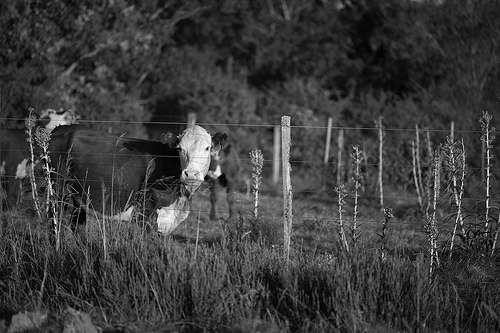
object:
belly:
[72, 193, 137, 222]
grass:
[255, 257, 337, 325]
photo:
[9, 6, 494, 325]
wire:
[241, 114, 346, 135]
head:
[168, 120, 218, 188]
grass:
[208, 246, 270, 297]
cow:
[45, 124, 227, 233]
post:
[274, 113, 295, 266]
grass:
[30, 223, 139, 329]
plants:
[94, 190, 140, 259]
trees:
[76, 62, 153, 121]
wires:
[33, 151, 282, 162]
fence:
[6, 94, 492, 279]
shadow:
[122, 138, 181, 166]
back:
[56, 121, 176, 154]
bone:
[66, 127, 80, 150]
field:
[21, 162, 494, 333]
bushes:
[10, 199, 251, 329]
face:
[173, 125, 213, 185]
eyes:
[175, 146, 211, 151]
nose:
[183, 167, 214, 178]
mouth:
[179, 175, 204, 189]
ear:
[211, 130, 229, 152]